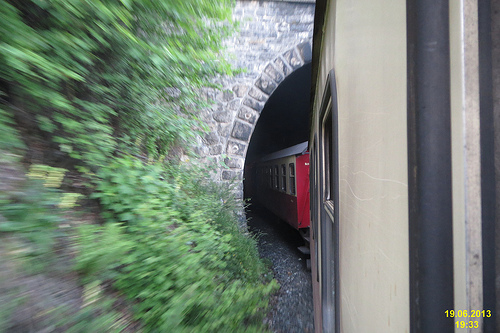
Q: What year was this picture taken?
A: 2013.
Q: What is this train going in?
A: Cave.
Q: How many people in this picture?
A: None.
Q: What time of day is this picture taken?
A: Daytime.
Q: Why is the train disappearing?
A: Going in cave.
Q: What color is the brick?
A: Gray.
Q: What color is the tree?
A: Green.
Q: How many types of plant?
A: One.